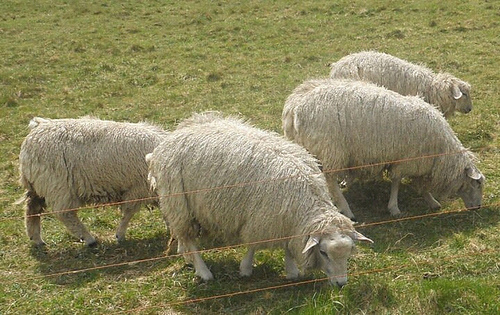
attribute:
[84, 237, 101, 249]
hoove — sheep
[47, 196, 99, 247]
leg — back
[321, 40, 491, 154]
sheep — standing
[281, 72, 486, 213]
sheep — standing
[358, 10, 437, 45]
field — unoccupied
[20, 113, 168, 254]
animal — group, eating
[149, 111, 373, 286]
animal — group, eating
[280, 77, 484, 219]
animal — group, eating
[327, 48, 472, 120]
animal — group, eating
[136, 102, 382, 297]
sheep — standing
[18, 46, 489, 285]
sheep — together, group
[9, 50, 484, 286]
white sheep — fluffy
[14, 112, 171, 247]
white sheep — fluffy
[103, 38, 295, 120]
grass — patchy, eaten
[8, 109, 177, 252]
sheep — white, fluffy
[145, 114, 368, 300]
sheep — together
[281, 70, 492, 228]
sheep — together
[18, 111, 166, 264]
sheep — together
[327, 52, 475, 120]
sheep — together